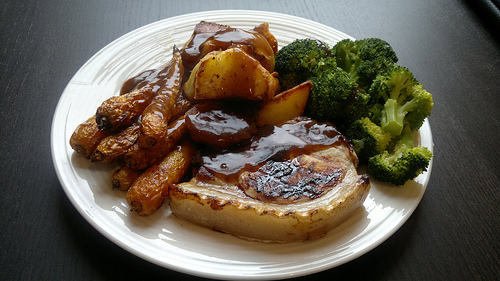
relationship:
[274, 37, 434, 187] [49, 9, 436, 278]
broccoli on plate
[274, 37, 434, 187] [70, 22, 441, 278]
broccoli on plate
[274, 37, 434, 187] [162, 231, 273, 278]
broccoli on plate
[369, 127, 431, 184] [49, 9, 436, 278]
broccoli on plate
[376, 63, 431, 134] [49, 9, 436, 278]
broccoli on plate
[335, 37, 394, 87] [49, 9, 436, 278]
broccoli on plate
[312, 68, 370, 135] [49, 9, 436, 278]
broccoli on plate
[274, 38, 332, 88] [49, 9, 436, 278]
broccoli on plate